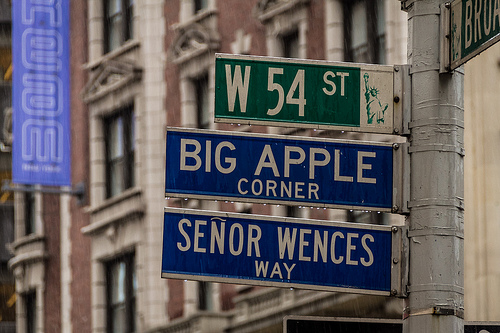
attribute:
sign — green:
[211, 58, 388, 128]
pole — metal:
[401, 0, 462, 330]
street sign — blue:
[161, 206, 396, 296]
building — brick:
[1, 0, 402, 331]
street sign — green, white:
[206, 46, 403, 138]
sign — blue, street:
[161, 210, 401, 299]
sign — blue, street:
[165, 125, 406, 204]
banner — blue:
[10, 106, 81, 233]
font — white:
[201, 223, 472, 318]